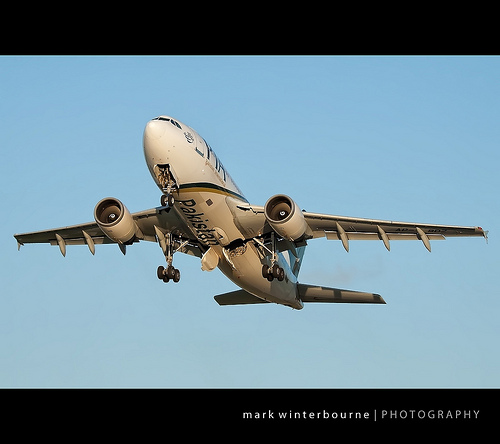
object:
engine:
[93, 196, 138, 244]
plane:
[14, 113, 489, 310]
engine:
[262, 194, 308, 243]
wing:
[223, 192, 493, 260]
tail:
[212, 279, 387, 310]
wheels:
[157, 266, 165, 280]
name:
[236, 408, 484, 421]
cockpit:
[142, 115, 196, 158]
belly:
[166, 193, 255, 265]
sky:
[0, 54, 500, 388]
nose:
[145, 117, 173, 133]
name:
[174, 199, 222, 246]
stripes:
[172, 187, 249, 201]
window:
[170, 119, 176, 126]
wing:
[14, 196, 178, 257]